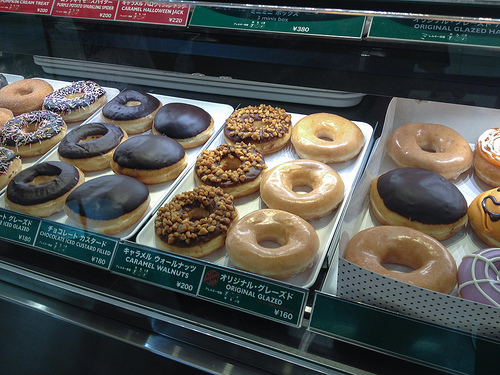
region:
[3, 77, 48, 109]
a plain cake doughnut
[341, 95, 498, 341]
a box of doughnuts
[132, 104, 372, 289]
a white tray of doughnuts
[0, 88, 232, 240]
a white tray of doughnuts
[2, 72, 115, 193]
a white tray of doughnuts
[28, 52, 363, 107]
a long white tray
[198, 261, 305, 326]
a doughnut price sign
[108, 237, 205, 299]
a doughnut price sign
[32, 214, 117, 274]
a doughnut price sign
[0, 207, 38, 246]
a doughnut price sign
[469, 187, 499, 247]
an orange and black frosted doughnut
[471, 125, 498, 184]
an orange frosted doughnut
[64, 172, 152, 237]
a chocolate frosted creme doughnut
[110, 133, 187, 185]
a chocolate frosted creme doughnut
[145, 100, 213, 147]
a chocolate frosted creme doughnut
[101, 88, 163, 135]
a chocolate frosted doughnut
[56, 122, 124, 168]
a chocolate frosted doughnut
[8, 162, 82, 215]
a chocolate frosted doughnut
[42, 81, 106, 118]
a chocolate frosted sprinkle doughnut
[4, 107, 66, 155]
a chocolate frosted sprinkle doughnut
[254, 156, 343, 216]
a plain glazed doughnut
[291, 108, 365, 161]
a plain glazed doughnut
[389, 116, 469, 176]
a plain glazed doughnut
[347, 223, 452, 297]
a plain glazed doughnut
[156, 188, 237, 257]
a chocolate and nut frosted doughnut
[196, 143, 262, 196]
a chocolate and nut frosted doughnut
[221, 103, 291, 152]
a chocolate and nut frosted doughnut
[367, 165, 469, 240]
a chocolate iced creme filled doughnut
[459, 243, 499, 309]
a pink and white doughnut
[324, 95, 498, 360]
a Krispy Kreme donut box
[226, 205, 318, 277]
an original glazed donut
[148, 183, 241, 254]
a caramel walnut donut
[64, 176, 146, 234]
a chocolate iced custard donut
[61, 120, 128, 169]
a chocolate iced glazed donut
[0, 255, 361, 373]
silver donut case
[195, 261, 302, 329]
a green donut title plackard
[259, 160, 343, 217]
a glazed donut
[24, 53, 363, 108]
a silver donut tray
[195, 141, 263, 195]
a caramel walnut donut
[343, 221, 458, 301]
glazed donut in a box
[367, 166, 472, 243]
cream filled donut with chocolate icing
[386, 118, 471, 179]
plane glazed donut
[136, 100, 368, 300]
half a dozen donuts on a platter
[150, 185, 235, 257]
chocolate iced donut with peanuts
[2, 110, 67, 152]
chocolate iced donut with sprinkles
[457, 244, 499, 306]
purple frosted donut with white icing design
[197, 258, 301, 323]
text on the front of the donut shelf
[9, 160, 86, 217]
donut with chocolate frosting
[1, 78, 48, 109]
plane donut with no frosting